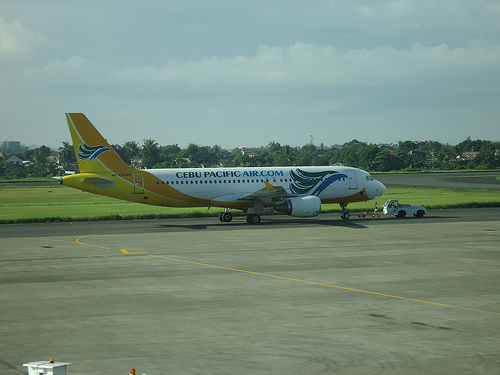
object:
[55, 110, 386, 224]
plane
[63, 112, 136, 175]
tail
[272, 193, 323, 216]
engine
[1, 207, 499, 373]
pavement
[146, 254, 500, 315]
lines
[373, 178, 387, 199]
nose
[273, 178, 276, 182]
windows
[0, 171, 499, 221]
grass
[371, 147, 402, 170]
trees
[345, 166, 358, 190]
door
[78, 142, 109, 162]
logo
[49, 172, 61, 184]
propeller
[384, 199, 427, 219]
truck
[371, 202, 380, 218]
person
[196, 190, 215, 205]
door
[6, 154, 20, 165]
house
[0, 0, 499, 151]
sky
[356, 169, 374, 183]
cock pit